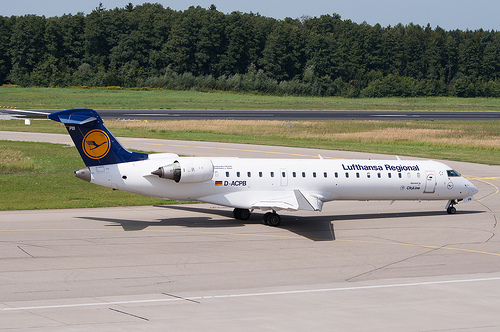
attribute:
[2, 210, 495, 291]
runway — clean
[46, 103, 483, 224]
aeroplane — white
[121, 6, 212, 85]
forest — green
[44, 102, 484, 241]
plane — white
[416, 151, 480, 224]
head — streamlined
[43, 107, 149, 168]
tail — blue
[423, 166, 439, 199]
door — closed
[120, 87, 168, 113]
grass — green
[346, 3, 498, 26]
sky — blue